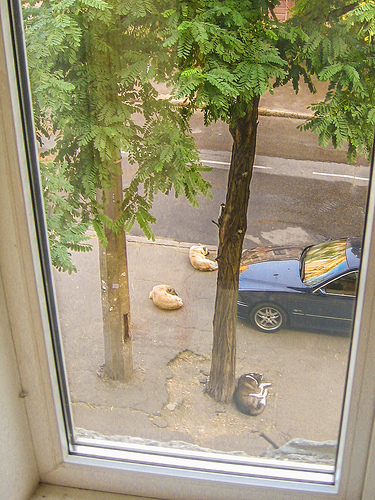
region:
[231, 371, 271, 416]
sleeping dog by tree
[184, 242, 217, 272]
sleeping dog by curb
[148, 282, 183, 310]
sleeping dog in middle of sidewalk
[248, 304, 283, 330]
the front wheel of the car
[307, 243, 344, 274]
the cars windsheild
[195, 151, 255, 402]
the truck of the tree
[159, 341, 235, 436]
the crack in the sidewalk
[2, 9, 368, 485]
The window itself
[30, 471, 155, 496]
the window sill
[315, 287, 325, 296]
the car's side view mirror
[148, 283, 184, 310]
a yellow lab curled up on sidewalk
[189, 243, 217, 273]
a yellow labe on the sidewalk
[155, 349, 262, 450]
a broken section of sidewalk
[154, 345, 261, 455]
a crumbled surface of the sidewalk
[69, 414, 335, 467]
broken glass across the window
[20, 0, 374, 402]
a tree visible out the window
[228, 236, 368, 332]
a car parked on the sidewalk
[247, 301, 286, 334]
front tire and wheel of the car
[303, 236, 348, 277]
reflection on the windshield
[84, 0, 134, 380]
a utility pole in the sidewalk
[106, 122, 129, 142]
leaves on the tree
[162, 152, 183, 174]
leaves on the tree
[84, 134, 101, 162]
leaves on the tree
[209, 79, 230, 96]
leaves on the tree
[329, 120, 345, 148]
leaves on the tree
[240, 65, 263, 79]
leaves on the tree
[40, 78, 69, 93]
leaves on the tree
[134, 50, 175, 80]
leaves on the tree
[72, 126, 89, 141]
leaves on the tree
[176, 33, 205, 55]
leaves on the tree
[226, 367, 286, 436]
the dog is sleeping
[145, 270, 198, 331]
the dog is sleeping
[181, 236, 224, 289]
the dog is sleeping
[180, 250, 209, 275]
the dog is sleeping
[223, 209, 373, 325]
the car is parked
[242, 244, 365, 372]
the car is parked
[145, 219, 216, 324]
Animals on the ground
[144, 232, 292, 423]
These animals are sleeping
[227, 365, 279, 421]
This animal is black and white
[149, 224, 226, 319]
Dogs are light brown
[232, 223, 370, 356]
A car on the sidewalk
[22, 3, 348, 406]
Tall trees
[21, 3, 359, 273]
The leaves are bright green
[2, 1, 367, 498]
A window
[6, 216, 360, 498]
Paint is white